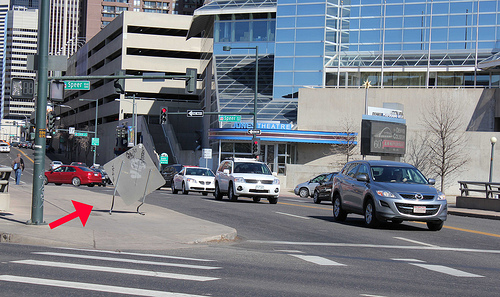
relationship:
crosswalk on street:
[15, 249, 191, 294] [203, 179, 478, 294]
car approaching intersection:
[331, 158, 449, 233] [266, 248, 498, 290]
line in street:
[289, 252, 348, 274] [2, 211, 498, 295]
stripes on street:
[1, 243, 238, 294] [1, 138, 496, 294]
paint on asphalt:
[292, 252, 341, 269] [6, 244, 498, 295]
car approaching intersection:
[208, 152, 286, 210] [6, 225, 481, 292]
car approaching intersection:
[331, 158, 449, 233] [4, 215, 482, 293]